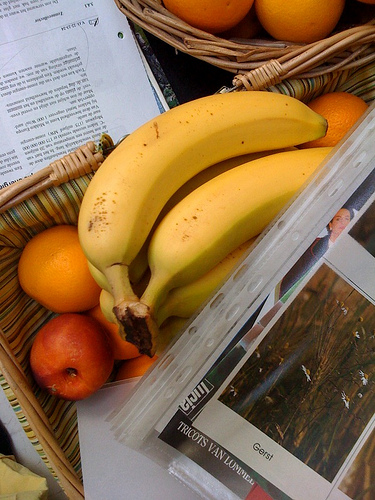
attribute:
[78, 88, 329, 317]
banana — bunch, spotted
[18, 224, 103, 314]
orange — unpeeled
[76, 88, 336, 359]
bananas — yellow, bunch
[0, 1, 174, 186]
paper — sheets, stacked, typed, white, small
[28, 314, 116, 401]
apple — red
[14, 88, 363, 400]
fruit — small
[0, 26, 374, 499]
basket — wood, brown, wicker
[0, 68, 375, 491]
cloth — striped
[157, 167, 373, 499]
paper — crumpled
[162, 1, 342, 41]
fruit — small